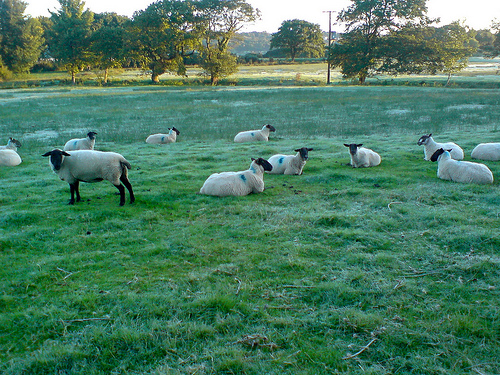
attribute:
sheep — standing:
[42, 149, 135, 206]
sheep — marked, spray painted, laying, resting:
[200, 158, 274, 196]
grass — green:
[2, 87, 496, 374]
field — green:
[0, 49, 493, 373]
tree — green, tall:
[41, 1, 103, 84]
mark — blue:
[238, 173, 250, 183]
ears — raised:
[436, 147, 454, 153]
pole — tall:
[326, 11, 332, 85]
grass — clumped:
[95, 295, 239, 365]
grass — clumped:
[432, 209, 495, 253]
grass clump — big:
[26, 294, 241, 368]